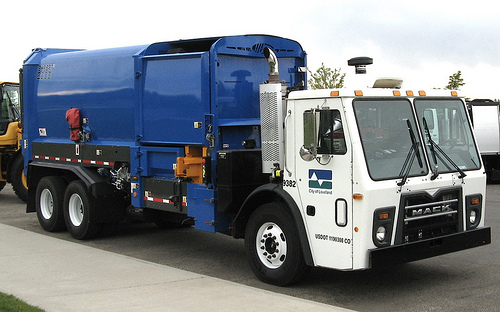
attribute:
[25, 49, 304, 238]
truck — blue, garbage, white, small, big, large, mack, trash, parked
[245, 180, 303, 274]
tire — black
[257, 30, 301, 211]
pipe — large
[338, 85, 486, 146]
windshield — black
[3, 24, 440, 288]
picture — day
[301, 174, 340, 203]
logo — blue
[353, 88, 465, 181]
window — large